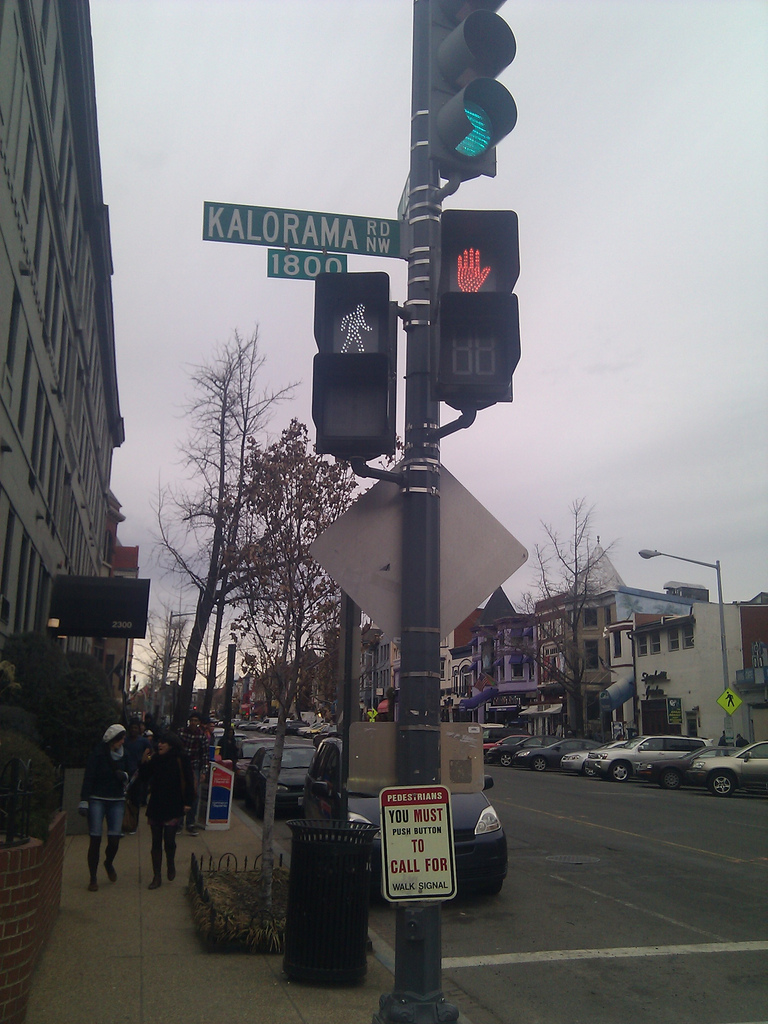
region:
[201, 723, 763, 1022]
silver minivan parked on road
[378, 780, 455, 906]
white sign with red and black writing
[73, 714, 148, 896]
woman wearing white beret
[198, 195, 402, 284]
green street sign with white writing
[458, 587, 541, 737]
building is pink and purple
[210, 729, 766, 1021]
white line in the road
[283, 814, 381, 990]
black wrought iron garbage can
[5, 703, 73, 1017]
green shrub in brick planter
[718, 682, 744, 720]
bright yellow pedestrian crossing sign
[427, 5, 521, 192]
traffic signal light is green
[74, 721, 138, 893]
woman in black boots on sidewalk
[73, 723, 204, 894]
two women walking on sidewalk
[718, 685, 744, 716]
green and black walking sign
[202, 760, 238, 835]
red white and blue newspaper stand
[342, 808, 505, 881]
clear headlights on front of blue car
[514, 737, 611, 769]
blue car parked on street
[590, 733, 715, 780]
grey car parked on street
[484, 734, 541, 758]
red car parked on street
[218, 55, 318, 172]
grey and white sky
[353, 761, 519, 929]
red and white sign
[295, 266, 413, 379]
white pedestrian walk signal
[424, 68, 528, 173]
traffic light is green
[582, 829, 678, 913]
road is dark grey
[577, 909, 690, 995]
white line on road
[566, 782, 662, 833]
yellow lines on road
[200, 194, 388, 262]
a street sign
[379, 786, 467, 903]
a sign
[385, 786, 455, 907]
a red and white sign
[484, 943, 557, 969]
a white line in the street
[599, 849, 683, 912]
the street is grey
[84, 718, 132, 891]
a person walking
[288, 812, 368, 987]
a trash can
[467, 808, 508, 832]
clear headlight on the car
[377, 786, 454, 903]
white sign with black and red lettering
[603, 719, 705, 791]
silver suv parked on the street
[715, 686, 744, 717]
yellow sign with black outline of person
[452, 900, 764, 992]
white line painted on the street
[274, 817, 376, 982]
black trashcan on the sidewalk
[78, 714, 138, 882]
woman wearing white knit hat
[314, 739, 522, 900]
black van parked on the street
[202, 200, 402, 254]
green and white street sign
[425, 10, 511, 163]
traffic signal with lit green light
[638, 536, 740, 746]
silver pole with street light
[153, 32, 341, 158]
Large body of skies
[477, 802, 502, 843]
Headlight of a car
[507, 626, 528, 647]
a window on a building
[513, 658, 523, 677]
a window on a building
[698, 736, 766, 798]
a car on a street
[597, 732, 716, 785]
a car on a street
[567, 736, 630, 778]
a car on a street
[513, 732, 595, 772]
a car on a street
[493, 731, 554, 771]
a car on a street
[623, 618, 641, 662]
a window on a building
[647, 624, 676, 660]
a window on a building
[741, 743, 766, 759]
glass is clean and clear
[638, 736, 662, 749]
glass is clean and clear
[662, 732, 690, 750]
glass is clean and clear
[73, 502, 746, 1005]
buildings and cars on sides of wide street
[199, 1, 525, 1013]
pole with traffic signals, address signs and traffic signs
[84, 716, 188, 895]
women walking while talking to each other